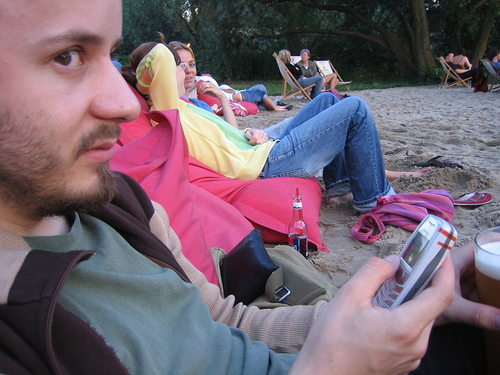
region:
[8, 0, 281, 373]
A line of people sitting on the beach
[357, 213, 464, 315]
A large silver colored cell phone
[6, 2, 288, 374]
A man in a green shirt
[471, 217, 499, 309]
A drinking glass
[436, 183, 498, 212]
A pink flip flop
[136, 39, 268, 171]
A girl in a green and yellow shirt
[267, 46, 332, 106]
A pair of people on white beach chairs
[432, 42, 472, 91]
A pair of people on white beach chairs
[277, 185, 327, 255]
A glass bottle in the sand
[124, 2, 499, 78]
A line of trees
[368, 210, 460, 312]
a grey and silver cellphone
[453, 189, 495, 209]
pink sandal in the sand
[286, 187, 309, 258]
half full bottle in the sand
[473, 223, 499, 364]
full glass of beer in mans hand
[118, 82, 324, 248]
large pink pillow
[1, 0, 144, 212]
man looking sideways at camera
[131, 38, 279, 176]
girl in yellow shirt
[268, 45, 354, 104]
two people sitting in beach chairs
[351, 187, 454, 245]
pink and purple town in sand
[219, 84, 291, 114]
person laying down on pillow in background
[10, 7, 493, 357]
man texting on phone in foreground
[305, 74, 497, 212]
sandy beach with people on it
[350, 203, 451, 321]
vintage grey nokia phone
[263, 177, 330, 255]
glass bottle with straw in it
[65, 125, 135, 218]
goatee on man in foreground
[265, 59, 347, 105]
people on far side in wooden chairs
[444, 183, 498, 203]
pink and white flip flop on sand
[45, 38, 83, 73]
brown eye of man staring at camera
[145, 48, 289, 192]
yellow sweater on woman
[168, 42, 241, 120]
blonde woman in blue with arm raised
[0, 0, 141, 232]
the profile of a creepy man's face.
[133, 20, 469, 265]
a woman sitting on a chair.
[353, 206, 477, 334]
a phone in a hand.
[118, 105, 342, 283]
a pick piece of clothing.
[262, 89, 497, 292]
a sandy ground covered in foot prints.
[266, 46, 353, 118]
a man sitting on a chair.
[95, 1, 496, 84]
a lush green forest.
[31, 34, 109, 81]
a right human eye.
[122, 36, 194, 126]
a female human head.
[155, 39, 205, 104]
a person sitting.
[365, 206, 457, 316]
grey plastic cell phone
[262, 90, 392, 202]
pair of blue jeans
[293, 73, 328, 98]
pair of blue jeans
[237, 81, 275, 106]
pair of blue jeans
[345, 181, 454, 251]
towel on the sand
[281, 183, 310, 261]
glass bottle with a straw in it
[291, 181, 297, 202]
small red straw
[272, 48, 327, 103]
person sitting in a chair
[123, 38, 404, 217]
person wearing blue jeans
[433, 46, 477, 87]
person sitting in a chair